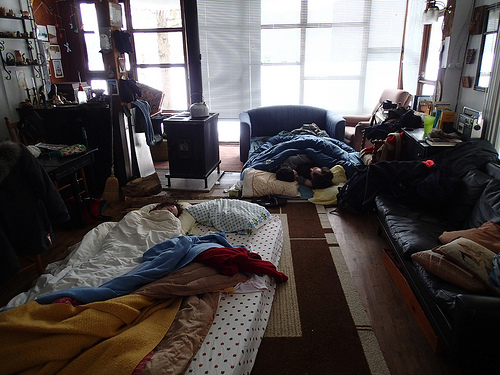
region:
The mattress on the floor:
[1, 198, 286, 374]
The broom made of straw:
[101, 83, 121, 208]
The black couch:
[361, 144, 498, 374]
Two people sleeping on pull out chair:
[246, 120, 346, 210]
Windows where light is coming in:
[39, 0, 424, 145]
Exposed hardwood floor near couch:
[329, 203, 443, 374]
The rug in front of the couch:
[248, 200, 390, 374]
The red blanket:
[198, 242, 292, 290]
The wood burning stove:
[159, 97, 223, 191]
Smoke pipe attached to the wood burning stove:
[176, 0, 207, 108]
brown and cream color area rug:
[68, 204, 360, 356]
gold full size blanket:
[0, 283, 202, 342]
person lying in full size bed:
[20, 203, 197, 348]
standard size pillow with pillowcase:
[157, 183, 287, 250]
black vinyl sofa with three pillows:
[360, 141, 481, 336]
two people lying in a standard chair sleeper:
[214, 114, 340, 208]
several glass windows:
[119, 20, 435, 120]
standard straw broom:
[70, 87, 165, 243]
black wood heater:
[135, 80, 243, 200]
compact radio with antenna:
[450, 95, 490, 150]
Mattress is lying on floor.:
[1, 190, 284, 372]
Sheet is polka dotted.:
[98, 196, 286, 373]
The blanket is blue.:
[30, 231, 252, 313]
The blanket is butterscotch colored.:
[1, 295, 190, 373]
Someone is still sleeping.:
[111, 197, 206, 269]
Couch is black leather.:
[361, 145, 499, 371]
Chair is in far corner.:
[338, 85, 417, 163]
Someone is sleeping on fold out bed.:
[242, 109, 357, 204]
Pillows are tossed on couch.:
[408, 216, 499, 295]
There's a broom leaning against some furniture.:
[96, 116, 128, 210]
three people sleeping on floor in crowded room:
[43, 41, 464, 303]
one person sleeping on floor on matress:
[75, 191, 277, 356]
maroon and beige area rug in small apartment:
[277, 199, 412, 370]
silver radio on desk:
[445, 101, 490, 143]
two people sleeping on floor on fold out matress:
[232, 91, 345, 202]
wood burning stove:
[143, 4, 228, 198]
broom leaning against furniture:
[91, 91, 122, 208]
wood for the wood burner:
[115, 171, 180, 202]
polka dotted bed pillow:
[186, 186, 264, 240]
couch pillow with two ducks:
[422, 221, 494, 298]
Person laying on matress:
[123, 189, 200, 309]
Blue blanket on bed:
[140, 222, 204, 295]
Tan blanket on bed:
[51, 290, 115, 350]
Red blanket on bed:
[187, 237, 279, 297]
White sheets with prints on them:
[183, 245, 255, 374]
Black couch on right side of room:
[410, 145, 464, 291]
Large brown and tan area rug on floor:
[248, 172, 388, 369]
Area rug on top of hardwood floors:
[283, 207, 395, 361]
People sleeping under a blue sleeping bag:
[236, 75, 358, 177]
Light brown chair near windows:
[338, 79, 420, 199]